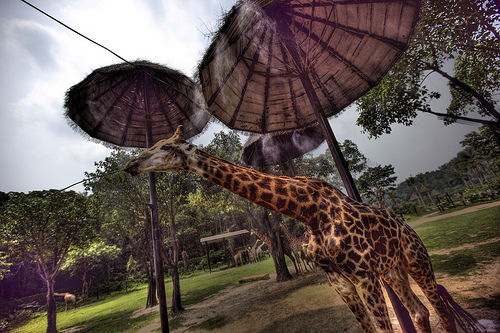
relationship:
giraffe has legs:
[131, 127, 468, 325] [323, 271, 466, 331]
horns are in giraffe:
[167, 121, 194, 156] [131, 127, 468, 325]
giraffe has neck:
[131, 127, 468, 325] [209, 148, 309, 230]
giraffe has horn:
[131, 127, 468, 325] [171, 121, 189, 142]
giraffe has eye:
[131, 127, 468, 325] [157, 142, 178, 154]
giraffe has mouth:
[131, 127, 468, 325] [120, 157, 146, 175]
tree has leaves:
[8, 184, 89, 330] [10, 191, 97, 250]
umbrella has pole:
[203, 5, 416, 134] [311, 88, 350, 183]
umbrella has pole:
[63, 58, 213, 123] [142, 191, 177, 328]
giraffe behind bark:
[250, 224, 266, 252] [267, 235, 296, 286]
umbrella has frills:
[63, 58, 213, 123] [67, 120, 93, 139]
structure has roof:
[198, 226, 255, 272] [198, 224, 257, 244]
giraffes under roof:
[230, 238, 269, 266] [198, 224, 257, 244]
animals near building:
[131, 127, 468, 325] [127, 188, 313, 311]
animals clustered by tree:
[123, 138, 428, 320] [8, 184, 89, 330]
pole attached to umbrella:
[142, 191, 177, 328] [69, 51, 214, 228]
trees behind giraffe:
[8, 184, 89, 330] [186, 120, 455, 321]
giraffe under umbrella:
[131, 127, 468, 325] [74, 33, 274, 314]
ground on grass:
[7, 198, 497, 332] [44, 200, 324, 300]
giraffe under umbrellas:
[131, 127, 468, 325] [70, 1, 410, 182]